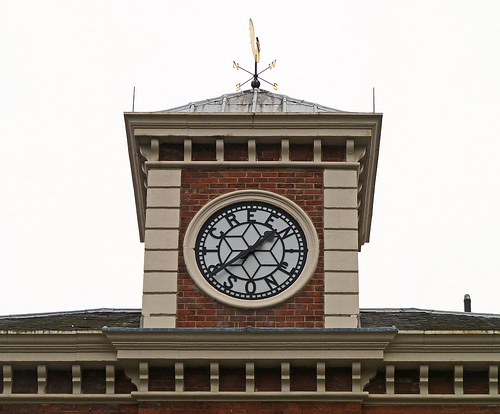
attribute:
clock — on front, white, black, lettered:
[181, 176, 326, 319]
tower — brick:
[128, 98, 379, 329]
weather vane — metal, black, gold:
[233, 23, 293, 93]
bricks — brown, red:
[303, 178, 323, 205]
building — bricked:
[7, 316, 163, 402]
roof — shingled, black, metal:
[369, 310, 498, 332]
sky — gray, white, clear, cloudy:
[328, 26, 363, 48]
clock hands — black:
[219, 219, 290, 279]